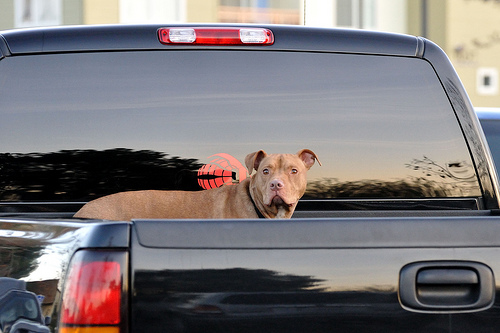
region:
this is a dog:
[80, 152, 327, 207]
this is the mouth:
[270, 194, 287, 203]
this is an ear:
[296, 147, 325, 172]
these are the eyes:
[254, 164, 309, 177]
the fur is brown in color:
[147, 196, 183, 209]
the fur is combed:
[126, 199, 156, 209]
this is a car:
[12, 22, 462, 304]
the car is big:
[32, 47, 434, 328]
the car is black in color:
[305, 275, 337, 293]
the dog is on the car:
[67, 138, 363, 247]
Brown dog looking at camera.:
[70, 148, 322, 219]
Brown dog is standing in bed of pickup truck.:
[0, 20, 498, 331]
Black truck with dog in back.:
[2, 22, 499, 332]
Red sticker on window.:
[0, 48, 484, 198]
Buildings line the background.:
[0, 0, 497, 107]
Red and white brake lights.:
[156, 25, 273, 46]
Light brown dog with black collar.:
[70, 147, 320, 221]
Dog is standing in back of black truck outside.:
[1, 1, 498, 331]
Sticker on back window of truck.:
[0, 22, 499, 332]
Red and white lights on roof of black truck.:
[0, 21, 499, 331]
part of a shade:
[252, 256, 275, 290]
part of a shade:
[253, 240, 290, 313]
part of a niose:
[258, 167, 284, 202]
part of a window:
[361, 151, 399, 183]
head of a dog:
[245, 130, 327, 212]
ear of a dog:
[243, 148, 270, 170]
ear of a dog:
[294, 147, 316, 172]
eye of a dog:
[262, 162, 277, 180]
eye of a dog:
[286, 161, 300, 173]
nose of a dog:
[263, 174, 286, 191]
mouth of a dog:
[259, 191, 306, 209]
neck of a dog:
[239, 175, 268, 219]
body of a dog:
[69, 177, 243, 232]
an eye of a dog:
[248, 165, 283, 184]